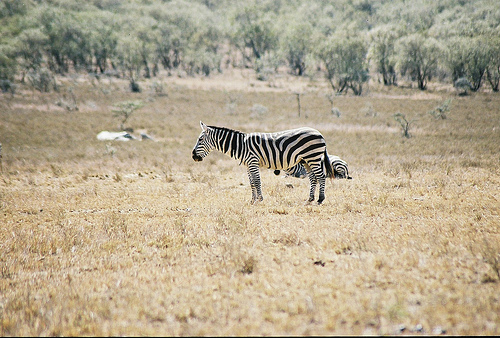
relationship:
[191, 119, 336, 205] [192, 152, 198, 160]
zebra has a snout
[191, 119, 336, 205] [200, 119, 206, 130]
zebra has a ear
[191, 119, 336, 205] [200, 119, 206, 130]
zebra has an ear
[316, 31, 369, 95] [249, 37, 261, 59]
tree has a branch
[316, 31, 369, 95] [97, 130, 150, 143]
tree by a rock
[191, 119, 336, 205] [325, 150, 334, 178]
zebra has a tail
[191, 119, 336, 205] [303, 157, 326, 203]
zebra has a leg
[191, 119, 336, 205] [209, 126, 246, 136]
zebra has a mane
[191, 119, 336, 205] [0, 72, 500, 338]
zebra in a field